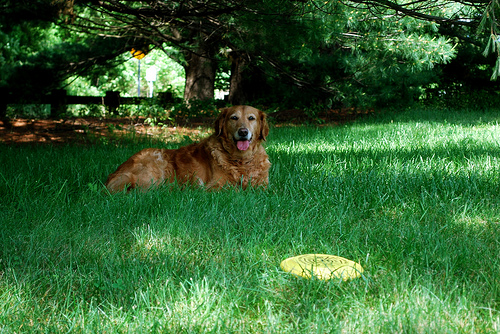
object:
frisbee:
[279, 252, 365, 280]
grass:
[0, 106, 499, 333]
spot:
[265, 122, 500, 150]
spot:
[338, 286, 499, 332]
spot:
[1, 268, 309, 334]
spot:
[132, 224, 178, 251]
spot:
[451, 205, 489, 230]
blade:
[1, 104, 499, 333]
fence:
[1, 83, 229, 116]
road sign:
[130, 47, 145, 59]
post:
[137, 59, 142, 95]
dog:
[104, 104, 273, 195]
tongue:
[236, 139, 251, 152]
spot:
[152, 148, 163, 161]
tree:
[0, 0, 493, 110]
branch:
[378, 1, 499, 28]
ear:
[260, 109, 268, 140]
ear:
[214, 107, 228, 137]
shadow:
[346, 105, 499, 128]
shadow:
[267, 145, 499, 161]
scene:
[0, 1, 497, 334]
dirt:
[2, 114, 335, 142]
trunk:
[185, 46, 215, 99]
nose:
[237, 128, 249, 135]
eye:
[247, 115, 254, 121]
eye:
[228, 114, 239, 121]